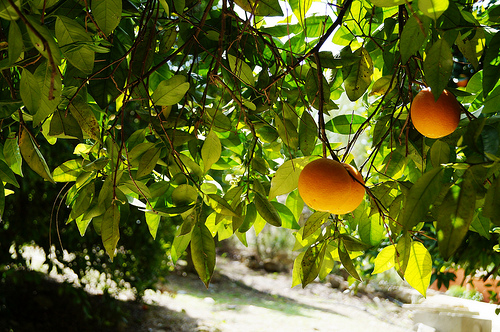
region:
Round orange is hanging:
[294, 151, 368, 216]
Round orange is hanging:
[402, 88, 465, 143]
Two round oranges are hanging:
[294, 84, 460, 220]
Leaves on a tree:
[5, 5, 497, 288]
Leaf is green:
[189, 228, 222, 288]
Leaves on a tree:
[1, 3, 166, 131]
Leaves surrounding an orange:
[2, 1, 499, 274]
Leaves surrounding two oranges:
[4, 0, 497, 280]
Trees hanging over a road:
[2, 5, 499, 285]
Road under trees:
[26, 231, 496, 327]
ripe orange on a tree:
[401, 77, 468, 139]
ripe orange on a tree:
[291, 154, 353, 216]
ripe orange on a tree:
[327, 161, 371, 216]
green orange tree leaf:
[190, 212, 220, 292]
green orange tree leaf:
[195, 117, 225, 183]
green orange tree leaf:
[147, 68, 196, 107]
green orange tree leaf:
[100, 196, 123, 267]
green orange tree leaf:
[15, 64, 40, 115]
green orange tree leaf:
[52, 14, 99, 75]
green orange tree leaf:
[132, 141, 165, 185]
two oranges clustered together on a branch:
[299, 153, 370, 220]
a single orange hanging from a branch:
[405, 80, 462, 144]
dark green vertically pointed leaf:
[420, 35, 456, 100]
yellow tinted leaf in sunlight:
[392, 243, 434, 293]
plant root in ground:
[112, 250, 169, 312]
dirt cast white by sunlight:
[213, 292, 350, 330]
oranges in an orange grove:
[255, 25, 477, 240]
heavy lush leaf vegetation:
[22, 36, 245, 264]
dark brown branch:
[313, 58, 325, 141]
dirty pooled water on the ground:
[420, 311, 493, 330]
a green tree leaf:
[47, 9, 109, 75]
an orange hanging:
[296, 145, 349, 210]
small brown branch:
[299, 43, 344, 177]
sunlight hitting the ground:
[184, 305, 301, 329]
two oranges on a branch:
[289, 146, 377, 220]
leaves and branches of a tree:
[6, 4, 230, 256]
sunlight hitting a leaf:
[389, 231, 436, 304]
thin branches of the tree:
[253, 0, 353, 102]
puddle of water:
[396, 292, 498, 329]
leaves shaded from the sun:
[19, 2, 296, 147]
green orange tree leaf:
[295, 108, 323, 156]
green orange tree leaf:
[324, 112, 375, 138]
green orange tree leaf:
[270, 108, 305, 157]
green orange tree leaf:
[370, 241, 402, 276]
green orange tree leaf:
[337, 237, 365, 289]